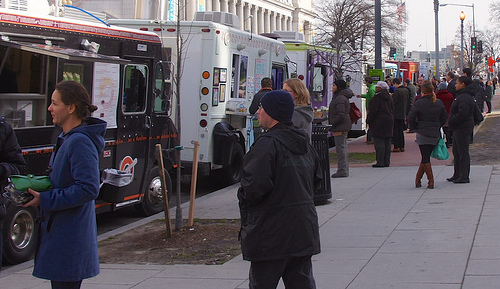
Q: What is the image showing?
A: It is showing a sidewalk.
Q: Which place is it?
A: It is a sidewalk.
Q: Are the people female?
A: No, they are both male and female.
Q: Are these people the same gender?
A: No, they are both male and female.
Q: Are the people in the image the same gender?
A: No, they are both male and female.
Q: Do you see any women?
A: Yes, there is a woman.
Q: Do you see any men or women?
A: Yes, there is a woman.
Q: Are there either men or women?
A: Yes, there is a woman.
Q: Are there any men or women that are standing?
A: Yes, the woman is standing.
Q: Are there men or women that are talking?
A: Yes, the woman is talking.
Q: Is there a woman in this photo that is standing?
A: Yes, there is a woman that is standing.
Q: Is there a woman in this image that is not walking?
A: Yes, there is a woman that is standing.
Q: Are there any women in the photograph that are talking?
A: Yes, there is a woman that is talking.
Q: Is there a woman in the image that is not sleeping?
A: Yes, there is a woman that is talking.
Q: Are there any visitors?
A: No, there are no visitors.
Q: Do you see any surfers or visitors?
A: No, there are no visitors or surfers.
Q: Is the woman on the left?
A: Yes, the woman is on the left of the image.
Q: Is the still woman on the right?
A: No, the woman is on the left of the image.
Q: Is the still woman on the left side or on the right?
A: The woman is on the left of the image.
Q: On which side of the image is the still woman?
A: The woman is on the left of the image.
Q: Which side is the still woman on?
A: The woman is on the left of the image.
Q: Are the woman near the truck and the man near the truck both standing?
A: Yes, both the woman and the man are standing.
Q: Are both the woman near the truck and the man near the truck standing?
A: Yes, both the woman and the man are standing.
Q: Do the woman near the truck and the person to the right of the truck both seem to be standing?
A: Yes, both the woman and the man are standing.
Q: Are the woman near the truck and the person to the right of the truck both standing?
A: Yes, both the woman and the man are standing.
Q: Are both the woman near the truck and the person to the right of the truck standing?
A: Yes, both the woman and the man are standing.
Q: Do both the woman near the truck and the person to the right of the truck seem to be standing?
A: Yes, both the woman and the man are standing.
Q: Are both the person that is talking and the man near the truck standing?
A: Yes, both the woman and the man are standing.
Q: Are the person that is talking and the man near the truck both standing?
A: Yes, both the woman and the man are standing.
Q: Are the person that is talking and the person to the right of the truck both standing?
A: Yes, both the woman and the man are standing.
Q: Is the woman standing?
A: Yes, the woman is standing.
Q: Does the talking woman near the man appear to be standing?
A: Yes, the woman is standing.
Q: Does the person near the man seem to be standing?
A: Yes, the woman is standing.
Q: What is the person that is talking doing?
A: The woman is standing.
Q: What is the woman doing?
A: The woman is standing.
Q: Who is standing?
A: The woman is standing.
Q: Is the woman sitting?
A: No, the woman is standing.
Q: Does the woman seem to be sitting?
A: No, the woman is standing.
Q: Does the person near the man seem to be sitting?
A: No, the woman is standing.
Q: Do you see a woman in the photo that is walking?
A: No, there is a woman but she is standing.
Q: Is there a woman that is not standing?
A: No, there is a woman but she is standing.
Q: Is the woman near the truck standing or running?
A: The woman is standing.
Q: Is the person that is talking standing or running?
A: The woman is standing.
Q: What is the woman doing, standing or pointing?
A: The woman is standing.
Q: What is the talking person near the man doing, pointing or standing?
A: The woman is standing.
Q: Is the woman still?
A: Yes, the woman is still.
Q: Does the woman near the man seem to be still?
A: Yes, the woman is still.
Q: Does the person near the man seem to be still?
A: Yes, the woman is still.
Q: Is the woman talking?
A: Yes, the woman is talking.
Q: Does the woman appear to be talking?
A: Yes, the woman is talking.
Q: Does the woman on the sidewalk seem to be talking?
A: Yes, the woman is talking.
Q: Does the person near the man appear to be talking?
A: Yes, the woman is talking.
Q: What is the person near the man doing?
A: The woman is talking.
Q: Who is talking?
A: The woman is talking.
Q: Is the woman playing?
A: No, the woman is talking.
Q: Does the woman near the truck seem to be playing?
A: No, the woman is talking.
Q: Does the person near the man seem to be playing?
A: No, the woman is talking.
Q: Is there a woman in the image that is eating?
A: No, there is a woman but she is talking.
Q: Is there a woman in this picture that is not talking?
A: No, there is a woman but she is talking.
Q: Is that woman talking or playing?
A: The woman is talking.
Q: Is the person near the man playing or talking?
A: The woman is talking.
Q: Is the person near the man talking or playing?
A: The woman is talking.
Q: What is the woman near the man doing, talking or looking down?
A: The woman is talking.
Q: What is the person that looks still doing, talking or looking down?
A: The woman is talking.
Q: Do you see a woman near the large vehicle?
A: Yes, there is a woman near the truck.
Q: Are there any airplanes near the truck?
A: No, there is a woman near the truck.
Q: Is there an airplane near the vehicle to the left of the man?
A: No, there is a woman near the truck.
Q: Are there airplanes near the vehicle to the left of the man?
A: No, there is a woman near the truck.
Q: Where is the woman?
A: The woman is on the side walk.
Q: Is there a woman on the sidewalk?
A: Yes, there is a woman on the sidewalk.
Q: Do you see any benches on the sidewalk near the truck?
A: No, there is a woman on the sidewalk.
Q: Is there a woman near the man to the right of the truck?
A: Yes, there is a woman near the man.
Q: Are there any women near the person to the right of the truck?
A: Yes, there is a woman near the man.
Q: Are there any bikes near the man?
A: No, there is a woman near the man.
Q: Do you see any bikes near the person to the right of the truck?
A: No, there is a woman near the man.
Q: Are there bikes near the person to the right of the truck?
A: No, there is a woman near the man.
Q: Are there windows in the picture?
A: Yes, there is a window.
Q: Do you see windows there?
A: Yes, there is a window.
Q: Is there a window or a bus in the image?
A: Yes, there is a window.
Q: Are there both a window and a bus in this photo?
A: No, there is a window but no buses.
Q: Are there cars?
A: No, there are no cars.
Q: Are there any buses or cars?
A: No, there are no cars or buses.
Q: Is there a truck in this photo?
A: Yes, there is a truck.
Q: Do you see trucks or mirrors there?
A: Yes, there is a truck.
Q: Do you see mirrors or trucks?
A: Yes, there is a truck.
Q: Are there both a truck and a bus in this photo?
A: No, there is a truck but no buses.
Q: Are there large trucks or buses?
A: Yes, there is a large truck.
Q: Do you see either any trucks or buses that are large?
A: Yes, the truck is large.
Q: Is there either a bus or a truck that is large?
A: Yes, the truck is large.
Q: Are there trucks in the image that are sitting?
A: Yes, there is a truck that is sitting.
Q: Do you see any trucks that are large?
A: Yes, there is a large truck.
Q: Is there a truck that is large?
A: Yes, there is a truck that is large.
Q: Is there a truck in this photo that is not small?
A: Yes, there is a large truck.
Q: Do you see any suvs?
A: No, there are no suvs.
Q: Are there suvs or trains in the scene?
A: No, there are no suvs or trains.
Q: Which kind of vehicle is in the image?
A: The vehicle is a truck.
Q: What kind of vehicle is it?
A: The vehicle is a truck.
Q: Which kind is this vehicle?
A: This is a truck.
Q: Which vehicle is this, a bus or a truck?
A: This is a truck.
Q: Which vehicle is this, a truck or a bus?
A: This is a truck.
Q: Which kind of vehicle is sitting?
A: The vehicle is a truck.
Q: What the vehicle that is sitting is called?
A: The vehicle is a truck.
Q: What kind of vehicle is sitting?
A: The vehicle is a truck.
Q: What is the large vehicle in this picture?
A: The vehicle is a truck.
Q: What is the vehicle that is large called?
A: The vehicle is a truck.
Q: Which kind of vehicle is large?
A: The vehicle is a truck.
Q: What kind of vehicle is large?
A: The vehicle is a truck.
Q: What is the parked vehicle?
A: The vehicle is a truck.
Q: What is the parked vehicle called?
A: The vehicle is a truck.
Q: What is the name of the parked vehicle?
A: The vehicle is a truck.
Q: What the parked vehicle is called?
A: The vehicle is a truck.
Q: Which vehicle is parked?
A: The vehicle is a truck.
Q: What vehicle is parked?
A: The vehicle is a truck.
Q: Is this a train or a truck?
A: This is a truck.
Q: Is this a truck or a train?
A: This is a truck.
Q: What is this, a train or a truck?
A: This is a truck.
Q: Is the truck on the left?
A: Yes, the truck is on the left of the image.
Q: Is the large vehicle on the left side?
A: Yes, the truck is on the left of the image.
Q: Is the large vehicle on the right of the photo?
A: No, the truck is on the left of the image.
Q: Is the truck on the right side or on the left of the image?
A: The truck is on the left of the image.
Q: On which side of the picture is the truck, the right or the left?
A: The truck is on the left of the image.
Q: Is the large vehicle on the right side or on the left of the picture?
A: The truck is on the left of the image.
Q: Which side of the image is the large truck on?
A: The truck is on the left of the image.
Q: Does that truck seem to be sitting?
A: Yes, the truck is sitting.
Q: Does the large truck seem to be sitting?
A: Yes, the truck is sitting.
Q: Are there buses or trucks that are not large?
A: No, there is a truck but it is large.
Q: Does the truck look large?
A: Yes, the truck is large.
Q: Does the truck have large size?
A: Yes, the truck is large.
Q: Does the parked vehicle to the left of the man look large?
A: Yes, the truck is large.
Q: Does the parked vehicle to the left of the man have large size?
A: Yes, the truck is large.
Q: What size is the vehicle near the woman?
A: The truck is large.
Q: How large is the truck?
A: The truck is large.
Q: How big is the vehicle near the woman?
A: The truck is large.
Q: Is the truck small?
A: No, the truck is large.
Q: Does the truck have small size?
A: No, the truck is large.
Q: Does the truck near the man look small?
A: No, the truck is large.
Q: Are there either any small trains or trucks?
A: No, there is a truck but it is large.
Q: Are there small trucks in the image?
A: No, there is a truck but it is large.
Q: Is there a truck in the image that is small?
A: No, there is a truck but it is large.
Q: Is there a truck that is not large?
A: No, there is a truck but it is large.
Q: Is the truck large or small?
A: The truck is large.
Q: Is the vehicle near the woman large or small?
A: The truck is large.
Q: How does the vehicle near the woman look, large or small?
A: The truck is large.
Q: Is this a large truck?
A: Yes, this is a large truck.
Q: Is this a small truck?
A: No, this is a large truck.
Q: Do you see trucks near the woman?
A: Yes, there is a truck near the woman.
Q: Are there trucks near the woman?
A: Yes, there is a truck near the woman.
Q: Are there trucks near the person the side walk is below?
A: Yes, there is a truck near the woman.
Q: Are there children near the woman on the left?
A: No, there is a truck near the woman.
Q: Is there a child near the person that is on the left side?
A: No, there is a truck near the woman.